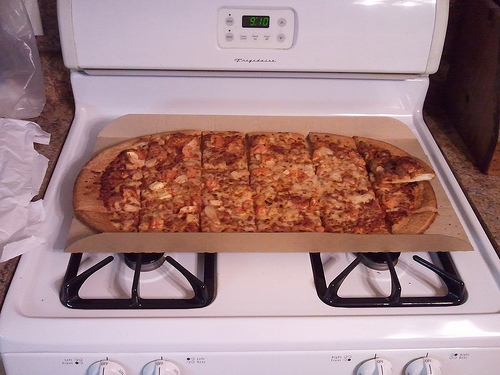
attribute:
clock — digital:
[216, 5, 295, 50]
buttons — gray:
[219, 9, 296, 52]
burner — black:
[61, 252, 215, 328]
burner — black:
[309, 262, 471, 312]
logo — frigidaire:
[234, 55, 278, 66]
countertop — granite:
[423, 107, 498, 256]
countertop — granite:
[0, 44, 75, 311]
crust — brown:
[404, 145, 441, 240]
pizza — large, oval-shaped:
[68, 127, 441, 236]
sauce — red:
[93, 131, 413, 236]